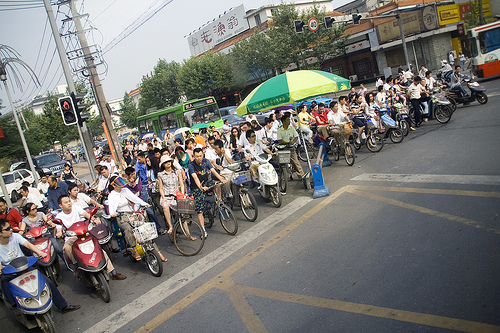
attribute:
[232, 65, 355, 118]
umbrella — green, yellow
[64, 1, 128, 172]
pole — electric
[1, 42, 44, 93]
wires — hanging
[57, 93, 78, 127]
light — red, yellow, black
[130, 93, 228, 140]
bus — green, bright green, background, red, white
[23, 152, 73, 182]
jeep — black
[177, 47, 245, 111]
trees — green, background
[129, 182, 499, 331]
lines — yellow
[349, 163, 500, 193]
markings — white, thick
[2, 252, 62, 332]
scooter — blue, silver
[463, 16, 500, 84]
bus — red, white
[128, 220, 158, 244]
basket — white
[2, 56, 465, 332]
people — crowds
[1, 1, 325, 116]
sky — powder blue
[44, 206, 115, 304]
bike — red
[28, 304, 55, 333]
wheel — small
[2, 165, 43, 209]
car — white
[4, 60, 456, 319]
group — large